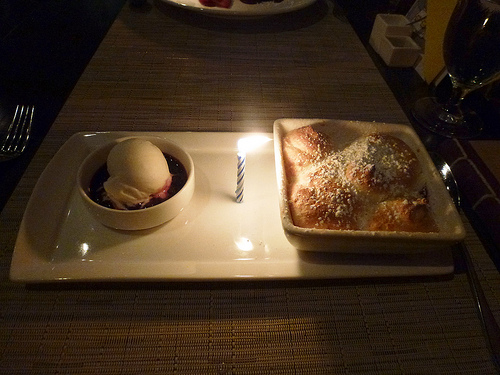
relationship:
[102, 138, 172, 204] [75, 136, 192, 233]
ice cream in bowl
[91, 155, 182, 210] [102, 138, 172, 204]
sauce on ice cream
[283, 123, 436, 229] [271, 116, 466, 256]
pastry in dish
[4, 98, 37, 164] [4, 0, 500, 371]
fork on table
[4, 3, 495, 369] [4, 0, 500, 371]
table runner on table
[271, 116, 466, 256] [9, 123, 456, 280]
dish on serving tray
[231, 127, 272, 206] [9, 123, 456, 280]
candle on serving tray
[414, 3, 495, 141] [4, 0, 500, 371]
glass on table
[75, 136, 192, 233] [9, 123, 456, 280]
bowl on serving tray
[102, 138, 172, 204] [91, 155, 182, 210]
ice cream with sauce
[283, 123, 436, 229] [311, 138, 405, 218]
pastry covered in powedered sugar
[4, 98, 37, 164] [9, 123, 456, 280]
fork by serving tray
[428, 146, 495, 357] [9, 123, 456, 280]
spoon next to serving tray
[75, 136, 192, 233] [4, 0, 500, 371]
bowl on table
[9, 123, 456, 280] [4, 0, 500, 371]
serving tray on table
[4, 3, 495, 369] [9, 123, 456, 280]
table runner under serving tray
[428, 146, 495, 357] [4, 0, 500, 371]
spoon on table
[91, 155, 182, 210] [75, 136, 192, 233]
sauce in bowl